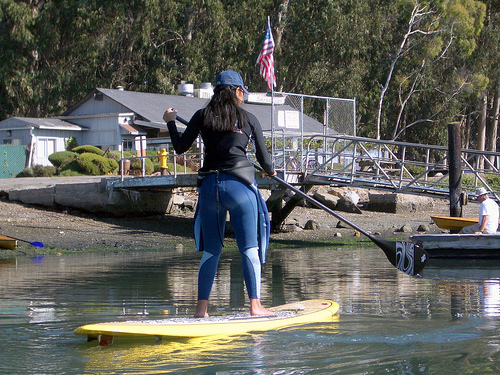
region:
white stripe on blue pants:
[232, 242, 277, 291]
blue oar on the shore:
[24, 234, 73, 261]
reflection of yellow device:
[125, 341, 242, 365]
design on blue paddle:
[387, 229, 432, 265]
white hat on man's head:
[463, 182, 494, 198]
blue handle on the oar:
[246, 157, 348, 210]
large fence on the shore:
[271, 82, 376, 174]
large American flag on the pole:
[242, 17, 310, 89]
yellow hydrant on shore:
[150, 146, 174, 173]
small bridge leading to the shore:
[287, 122, 474, 211]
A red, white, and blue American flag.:
[255, 17, 278, 90]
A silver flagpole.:
[266, 14, 276, 168]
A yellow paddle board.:
[76, 292, 347, 356]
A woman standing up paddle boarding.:
[72, 62, 428, 335]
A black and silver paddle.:
[169, 102, 431, 277]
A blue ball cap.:
[208, 71, 254, 96]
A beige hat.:
[477, 181, 489, 196]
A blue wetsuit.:
[192, 164, 270, 300]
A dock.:
[411, 215, 498, 260]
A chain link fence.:
[272, 94, 354, 171]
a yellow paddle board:
[76, 295, 338, 347]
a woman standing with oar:
[163, 68, 432, 318]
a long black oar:
[164, 108, 431, 280]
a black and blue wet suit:
[169, 99, 275, 301]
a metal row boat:
[406, 229, 498, 264]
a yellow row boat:
[426, 211, 477, 229]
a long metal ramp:
[296, 131, 498, 206]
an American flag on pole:
[253, 14, 276, 159]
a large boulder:
[338, 188, 368, 213]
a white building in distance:
[4, 87, 344, 173]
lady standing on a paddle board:
[78, 41, 446, 361]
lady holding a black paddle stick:
[64, 43, 459, 358]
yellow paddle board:
[68, 292, 369, 351]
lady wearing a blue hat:
[148, 35, 306, 332]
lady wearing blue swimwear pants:
[154, 45, 293, 322]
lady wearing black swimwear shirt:
[148, 54, 301, 327]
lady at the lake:
[22, 42, 472, 370]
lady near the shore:
[7, 11, 487, 373]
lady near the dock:
[12, 6, 492, 370]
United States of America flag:
[245, 9, 325, 177]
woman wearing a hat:
[210, 65, 270, 125]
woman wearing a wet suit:
[187, 160, 268, 300]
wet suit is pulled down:
[165, 157, 283, 288]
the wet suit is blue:
[190, 170, 268, 307]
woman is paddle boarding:
[20, 22, 435, 355]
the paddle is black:
[170, 110, 431, 288]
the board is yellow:
[50, 290, 356, 353]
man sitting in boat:
[451, 176, 497, 256]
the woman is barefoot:
[175, 288, 282, 334]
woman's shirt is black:
[161, 96, 271, 192]